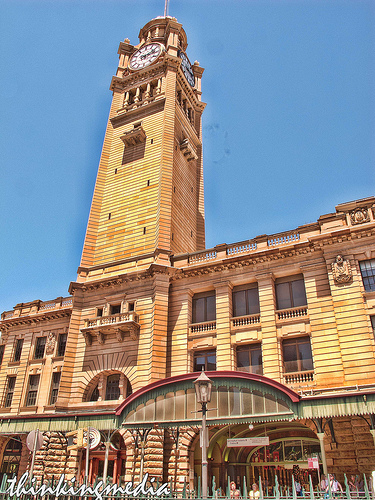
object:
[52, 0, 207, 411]
tower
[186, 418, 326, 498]
archway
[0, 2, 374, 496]
building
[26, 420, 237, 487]
columns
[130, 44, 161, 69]
clock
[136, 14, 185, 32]
roof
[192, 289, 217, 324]
windows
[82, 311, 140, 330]
balcony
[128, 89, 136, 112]
window slits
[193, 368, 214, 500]
light pole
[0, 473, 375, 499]
fence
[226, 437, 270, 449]
sign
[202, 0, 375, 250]
sky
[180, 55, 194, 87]
two clocks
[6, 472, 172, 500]
signature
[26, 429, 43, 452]
back of sign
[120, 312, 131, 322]
rails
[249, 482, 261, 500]
person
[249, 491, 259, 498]
white shirt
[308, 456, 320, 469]
red and white sign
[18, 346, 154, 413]
architecture